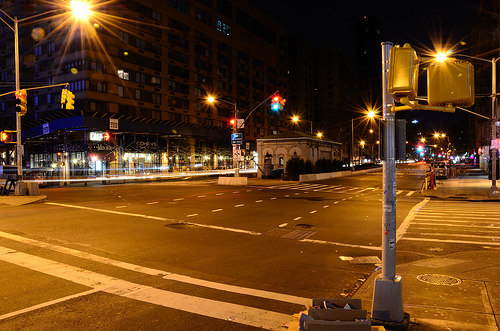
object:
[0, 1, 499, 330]
street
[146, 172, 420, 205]
crosswalk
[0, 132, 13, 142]
sign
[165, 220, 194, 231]
sewer hole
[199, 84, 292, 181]
street light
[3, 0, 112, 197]
street light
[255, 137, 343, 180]
building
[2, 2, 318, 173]
building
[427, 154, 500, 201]
sidewalk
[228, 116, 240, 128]
stop light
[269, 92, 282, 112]
stop light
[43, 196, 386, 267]
line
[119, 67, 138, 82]
window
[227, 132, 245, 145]
traffic sign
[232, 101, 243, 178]
pole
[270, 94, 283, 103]
red light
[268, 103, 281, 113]
green light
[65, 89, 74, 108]
pedestrian signal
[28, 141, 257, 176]
shop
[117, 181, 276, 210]
dotted line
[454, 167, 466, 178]
box